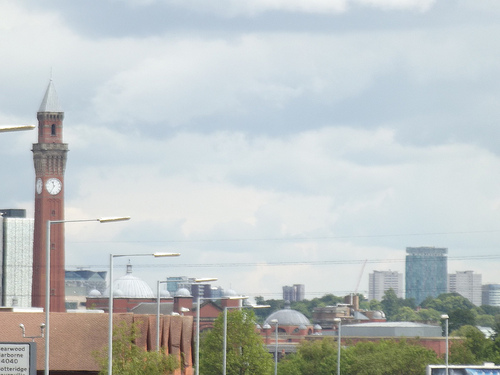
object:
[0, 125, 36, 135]
bird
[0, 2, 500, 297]
sky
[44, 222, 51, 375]
post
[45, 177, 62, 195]
clock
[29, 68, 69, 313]
tower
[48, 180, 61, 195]
hands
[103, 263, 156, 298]
roof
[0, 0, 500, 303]
clouds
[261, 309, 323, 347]
building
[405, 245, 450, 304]
building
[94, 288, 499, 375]
trees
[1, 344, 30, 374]
sign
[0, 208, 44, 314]
building